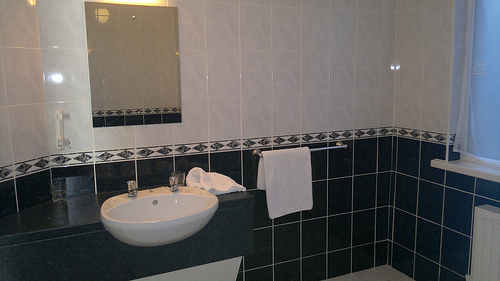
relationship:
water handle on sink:
[126, 180, 138, 195] [92, 185, 220, 248]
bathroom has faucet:
[0, 1, 496, 279] [165, 168, 185, 192]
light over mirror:
[85, 3, 177, 10] [83, 1, 181, 130]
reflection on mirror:
[87, 3, 181, 130] [80, 0, 190, 132]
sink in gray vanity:
[96, 185, 220, 248] [3, 182, 256, 278]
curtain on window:
[450, 0, 500, 166] [450, 4, 498, 167]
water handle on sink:
[126, 180, 138, 196] [96, 185, 220, 248]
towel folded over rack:
[256, 146, 315, 221] [242, 138, 351, 161]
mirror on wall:
[83, 1, 182, 129] [212, 17, 429, 120]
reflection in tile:
[50, 71, 64, 85] [241, 98, 270, 138]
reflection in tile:
[50, 71, 64, 85] [175, 95, 206, 143]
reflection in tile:
[50, 71, 64, 85] [46, 103, 93, 153]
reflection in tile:
[50, 71, 64, 85] [43, 48, 90, 103]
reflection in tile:
[50, 71, 64, 85] [37, 0, 85, 48]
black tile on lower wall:
[0, 133, 497, 279] [1, 105, 484, 265]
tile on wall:
[0, 0, 499, 281] [0, 1, 496, 279]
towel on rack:
[246, 146, 321, 231] [242, 132, 362, 160]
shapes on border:
[266, 124, 411, 144] [11, 123, 448, 168]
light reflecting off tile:
[46, 62, 66, 101] [48, 54, 94, 115]